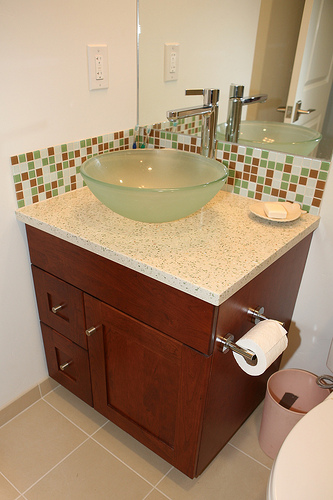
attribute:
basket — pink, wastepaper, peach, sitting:
[257, 362, 331, 465]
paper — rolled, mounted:
[232, 318, 290, 380]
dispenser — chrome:
[217, 307, 299, 360]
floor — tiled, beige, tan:
[0, 381, 277, 499]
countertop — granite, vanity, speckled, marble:
[15, 149, 320, 306]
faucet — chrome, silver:
[166, 87, 220, 157]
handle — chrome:
[185, 87, 223, 105]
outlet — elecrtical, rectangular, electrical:
[86, 43, 111, 94]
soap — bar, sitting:
[267, 201, 288, 220]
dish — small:
[242, 200, 302, 224]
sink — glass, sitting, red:
[77, 148, 230, 225]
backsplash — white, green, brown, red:
[8, 125, 329, 217]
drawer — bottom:
[40, 322, 93, 408]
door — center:
[84, 294, 206, 479]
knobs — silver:
[48, 310, 94, 373]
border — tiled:
[0, 377, 64, 435]